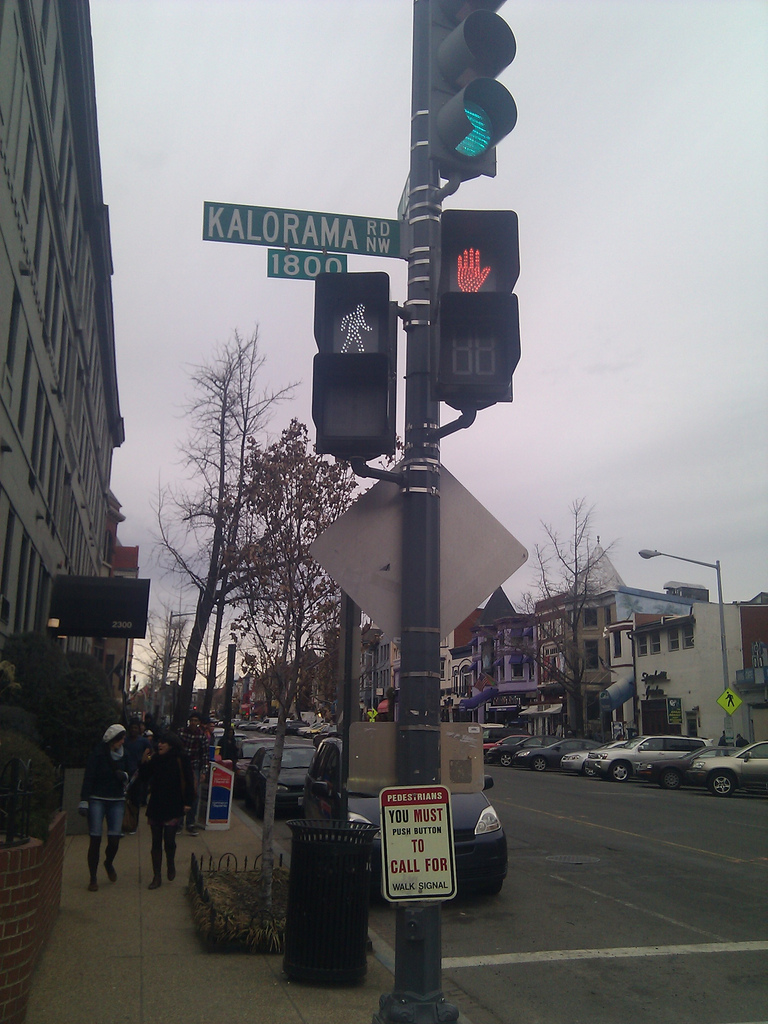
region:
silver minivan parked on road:
[201, 723, 763, 1022]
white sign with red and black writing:
[378, 780, 455, 906]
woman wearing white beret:
[73, 714, 148, 896]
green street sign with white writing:
[198, 195, 402, 284]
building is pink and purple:
[458, 587, 541, 737]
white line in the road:
[210, 729, 766, 1021]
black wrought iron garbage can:
[283, 814, 381, 990]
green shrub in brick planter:
[5, 703, 73, 1017]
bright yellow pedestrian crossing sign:
[718, 682, 744, 720]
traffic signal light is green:
[427, 5, 521, 192]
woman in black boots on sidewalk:
[74, 721, 138, 893]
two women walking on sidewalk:
[73, 723, 204, 894]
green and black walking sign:
[718, 685, 744, 716]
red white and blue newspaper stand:
[202, 760, 238, 835]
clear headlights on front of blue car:
[342, 808, 505, 881]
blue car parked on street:
[514, 737, 611, 769]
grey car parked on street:
[590, 733, 715, 780]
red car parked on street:
[484, 734, 541, 758]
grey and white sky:
[218, 55, 318, 172]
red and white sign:
[353, 761, 519, 929]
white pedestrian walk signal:
[295, 266, 413, 379]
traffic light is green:
[424, 68, 528, 173]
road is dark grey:
[582, 829, 678, 913]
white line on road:
[577, 909, 690, 995]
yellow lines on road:
[566, 782, 662, 833]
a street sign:
[200, 194, 388, 262]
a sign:
[379, 786, 467, 903]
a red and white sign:
[385, 786, 455, 907]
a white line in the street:
[484, 943, 557, 969]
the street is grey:
[599, 849, 683, 912]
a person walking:
[84, 718, 132, 891]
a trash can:
[288, 812, 368, 987]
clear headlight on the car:
[467, 808, 508, 832]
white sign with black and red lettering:
[377, 786, 454, 903]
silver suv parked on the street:
[603, 719, 705, 791]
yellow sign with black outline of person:
[715, 686, 744, 717]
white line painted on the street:
[452, 900, 764, 992]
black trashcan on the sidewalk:
[274, 817, 376, 982]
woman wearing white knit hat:
[78, 714, 138, 882]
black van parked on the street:
[314, 739, 522, 900]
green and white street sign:
[202, 200, 402, 254]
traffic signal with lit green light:
[425, 10, 511, 163]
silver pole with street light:
[638, 536, 740, 746]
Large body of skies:
[153, 32, 341, 158]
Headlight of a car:
[477, 802, 502, 843]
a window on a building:
[507, 626, 528, 647]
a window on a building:
[513, 658, 523, 677]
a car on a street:
[698, 736, 766, 798]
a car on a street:
[597, 732, 716, 785]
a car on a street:
[567, 736, 630, 778]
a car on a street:
[513, 732, 595, 772]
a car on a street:
[493, 731, 554, 771]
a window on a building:
[623, 618, 641, 662]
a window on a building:
[647, 624, 676, 660]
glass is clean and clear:
[741, 743, 766, 759]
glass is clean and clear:
[638, 736, 662, 749]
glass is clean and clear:
[662, 732, 690, 750]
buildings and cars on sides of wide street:
[73, 502, 746, 1005]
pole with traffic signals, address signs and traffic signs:
[199, 1, 525, 1013]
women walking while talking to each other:
[84, 716, 188, 895]